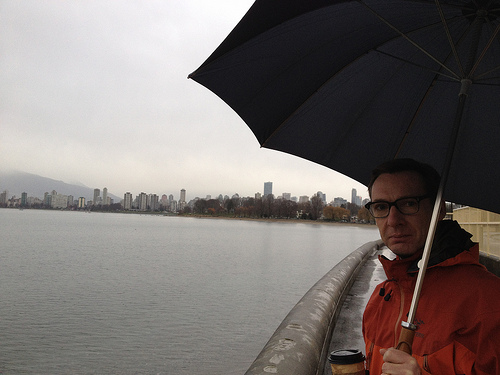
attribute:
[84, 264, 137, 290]
water — calm, part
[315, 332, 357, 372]
cup — disposable, top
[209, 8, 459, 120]
umbrella — open, black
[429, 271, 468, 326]
coat — orange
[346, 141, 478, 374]
man — standingy, standing, looking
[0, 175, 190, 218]
buildings — tall, distant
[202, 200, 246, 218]
trees — distant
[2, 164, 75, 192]
mountain — covered, misty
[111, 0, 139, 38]
sky — part